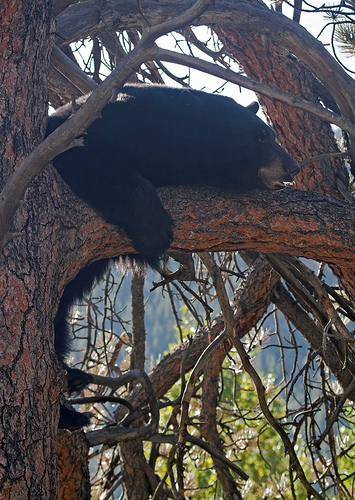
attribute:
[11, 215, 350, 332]
pine — dead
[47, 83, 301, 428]
bear — black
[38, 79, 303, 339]
bear — black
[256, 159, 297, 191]
mouth — open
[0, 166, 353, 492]
pine — Ponderosa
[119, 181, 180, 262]
paw — black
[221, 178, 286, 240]
tree — big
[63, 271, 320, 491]
branches — dead, tangled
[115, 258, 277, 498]
branch — tree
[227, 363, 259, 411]
foliage — green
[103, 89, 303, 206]
bear — black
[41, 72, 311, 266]
bear — black, tired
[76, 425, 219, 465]
tree — big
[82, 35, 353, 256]
tree — big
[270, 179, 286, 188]
tongue — pink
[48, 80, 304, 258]
bear — adult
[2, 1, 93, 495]
tree — dead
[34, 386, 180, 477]
tree — big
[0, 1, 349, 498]
tree — big, dead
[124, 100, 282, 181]
bear — black